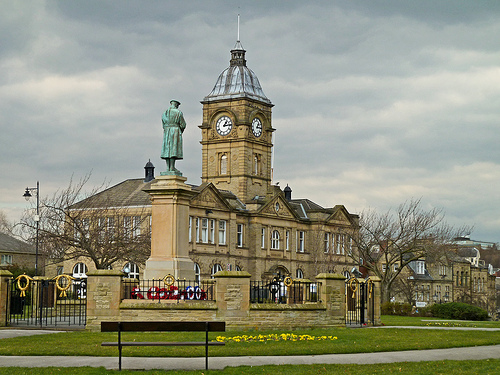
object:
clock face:
[213, 115, 235, 136]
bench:
[98, 316, 228, 369]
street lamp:
[22, 181, 41, 278]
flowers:
[329, 333, 340, 341]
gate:
[3, 273, 85, 330]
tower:
[200, 9, 275, 192]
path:
[0, 343, 497, 369]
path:
[367, 325, 498, 332]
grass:
[0, 314, 499, 355]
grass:
[3, 357, 499, 373]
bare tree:
[341, 197, 471, 312]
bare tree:
[11, 170, 151, 280]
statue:
[158, 98, 189, 175]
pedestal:
[143, 173, 196, 280]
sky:
[16, 91, 126, 159]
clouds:
[0, 61, 146, 121]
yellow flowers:
[256, 335, 264, 340]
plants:
[213, 333, 224, 341]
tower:
[139, 175, 199, 299]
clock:
[250, 115, 264, 139]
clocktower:
[201, 11, 274, 182]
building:
[61, 12, 379, 326]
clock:
[211, 115, 232, 135]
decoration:
[53, 273, 73, 299]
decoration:
[13, 273, 31, 297]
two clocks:
[202, 109, 272, 145]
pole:
[230, 9, 243, 49]